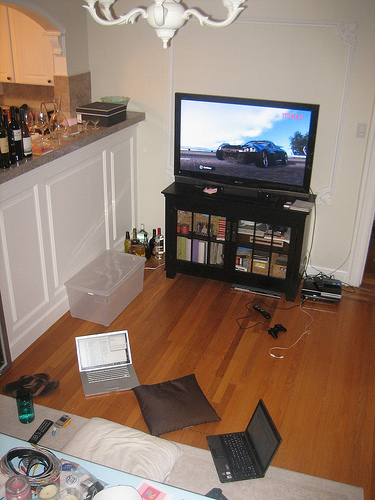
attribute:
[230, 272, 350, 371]
machine — gaming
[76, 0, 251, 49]
lighting fixture — white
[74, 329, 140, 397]
laptop — silver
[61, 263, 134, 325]
storage box — clear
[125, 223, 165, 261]
bottles — alcohol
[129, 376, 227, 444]
pillow — brown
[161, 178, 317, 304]
stand — tv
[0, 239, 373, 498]
floor — wooden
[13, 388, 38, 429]
controller — green, remote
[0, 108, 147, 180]
counter — granite